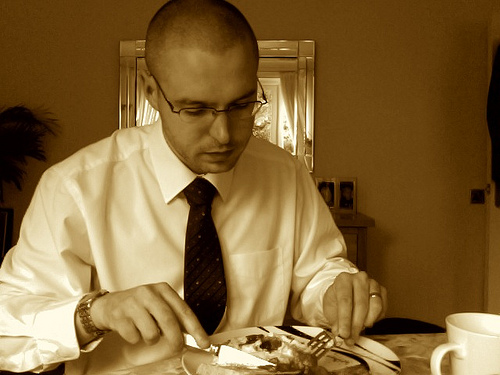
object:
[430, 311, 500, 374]
cup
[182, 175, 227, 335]
tie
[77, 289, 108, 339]
watch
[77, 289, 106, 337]
wrist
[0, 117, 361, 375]
shirt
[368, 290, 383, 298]
ring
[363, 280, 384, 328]
finger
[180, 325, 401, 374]
plate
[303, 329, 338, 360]
fork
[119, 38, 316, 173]
frame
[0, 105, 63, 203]
plant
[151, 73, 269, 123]
eye glasses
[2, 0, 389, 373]
man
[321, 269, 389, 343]
hand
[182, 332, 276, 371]
knife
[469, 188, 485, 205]
light switch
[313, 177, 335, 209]
picture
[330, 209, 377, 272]
cabinet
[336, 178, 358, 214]
picture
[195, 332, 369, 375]
food